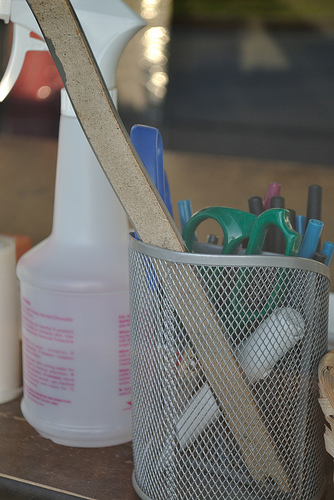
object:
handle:
[182, 200, 299, 340]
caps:
[304, 182, 320, 253]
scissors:
[129, 123, 173, 300]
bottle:
[0, 0, 159, 448]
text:
[18, 298, 76, 406]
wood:
[24, 1, 291, 493]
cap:
[248, 195, 265, 215]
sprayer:
[0, 0, 146, 450]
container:
[124, 230, 333, 500]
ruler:
[23, 0, 291, 495]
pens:
[304, 183, 323, 255]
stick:
[174, 307, 305, 454]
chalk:
[239, 306, 307, 383]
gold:
[135, 44, 199, 101]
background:
[0, 0, 332, 499]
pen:
[300, 217, 323, 257]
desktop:
[0, 375, 333, 499]